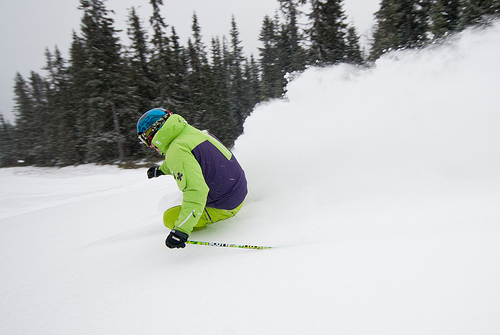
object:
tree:
[77, 0, 136, 166]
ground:
[0, 167, 495, 335]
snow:
[4, 258, 361, 331]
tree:
[9, 68, 30, 160]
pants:
[163, 201, 246, 232]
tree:
[48, 44, 70, 164]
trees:
[373, 0, 424, 49]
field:
[0, 139, 499, 330]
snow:
[440, 29, 500, 335]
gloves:
[165, 229, 190, 249]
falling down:
[137, 107, 249, 249]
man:
[137, 107, 248, 248]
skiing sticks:
[186, 240, 274, 250]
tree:
[222, 10, 247, 123]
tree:
[342, 24, 362, 66]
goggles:
[137, 112, 173, 148]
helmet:
[137, 108, 174, 148]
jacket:
[150, 113, 248, 234]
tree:
[257, 12, 287, 99]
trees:
[146, 0, 183, 100]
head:
[136, 108, 178, 156]